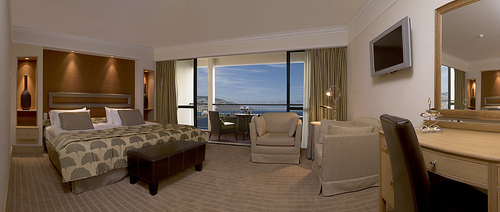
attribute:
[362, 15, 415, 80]
television — flat, mounted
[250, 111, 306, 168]
chair — beige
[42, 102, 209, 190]
bed — large, neat, made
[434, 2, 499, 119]
mirror — large, square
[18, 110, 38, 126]
shelf — recessed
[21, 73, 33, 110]
vase — dark, decorative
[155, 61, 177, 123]
curtains — tan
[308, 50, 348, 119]
curtains — tan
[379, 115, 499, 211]
desk — wooden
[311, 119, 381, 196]
couch — beige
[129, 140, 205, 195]
bench — wooden, dark, wood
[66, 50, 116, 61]
lights — on, mounted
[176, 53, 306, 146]
doors — large